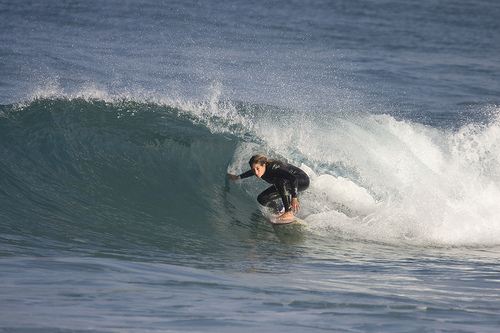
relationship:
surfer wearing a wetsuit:
[224, 152, 310, 218] [244, 163, 301, 209]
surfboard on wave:
[264, 208, 308, 226] [0, 89, 498, 247]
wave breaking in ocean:
[0, 89, 498, 247] [1, 0, 499, 333]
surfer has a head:
[224, 152, 310, 218] [248, 154, 268, 180]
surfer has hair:
[224, 152, 310, 218] [247, 155, 283, 163]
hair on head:
[247, 155, 283, 163] [248, 154, 268, 180]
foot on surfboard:
[275, 213, 295, 222] [264, 208, 308, 226]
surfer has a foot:
[224, 152, 310, 218] [275, 213, 295, 222]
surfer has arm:
[224, 152, 310, 218] [278, 167, 297, 200]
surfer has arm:
[224, 152, 310, 218] [240, 172, 256, 179]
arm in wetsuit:
[278, 167, 297, 200] [244, 163, 301, 209]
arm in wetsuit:
[240, 172, 256, 179] [244, 163, 301, 209]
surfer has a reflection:
[224, 152, 310, 218] [249, 214, 306, 249]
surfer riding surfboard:
[224, 152, 310, 218] [264, 208, 308, 226]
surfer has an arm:
[224, 152, 310, 218] [278, 167, 297, 200]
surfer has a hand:
[224, 152, 310, 218] [288, 203, 301, 214]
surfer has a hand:
[224, 152, 310, 218] [227, 172, 237, 181]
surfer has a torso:
[224, 152, 310, 218] [269, 167, 297, 181]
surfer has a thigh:
[224, 152, 310, 218] [283, 177, 308, 187]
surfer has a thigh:
[224, 152, 310, 218] [264, 188, 283, 198]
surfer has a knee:
[224, 152, 310, 218] [275, 177, 286, 187]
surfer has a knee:
[224, 152, 310, 218] [256, 194, 267, 205]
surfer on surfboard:
[224, 152, 310, 218] [264, 208, 308, 226]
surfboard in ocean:
[264, 208, 308, 226] [1, 0, 499, 333]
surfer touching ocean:
[224, 152, 310, 218] [1, 0, 499, 333]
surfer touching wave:
[224, 152, 310, 218] [0, 89, 498, 247]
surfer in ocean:
[224, 152, 310, 218] [1, 0, 499, 333]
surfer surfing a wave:
[224, 152, 310, 218] [0, 89, 498, 247]